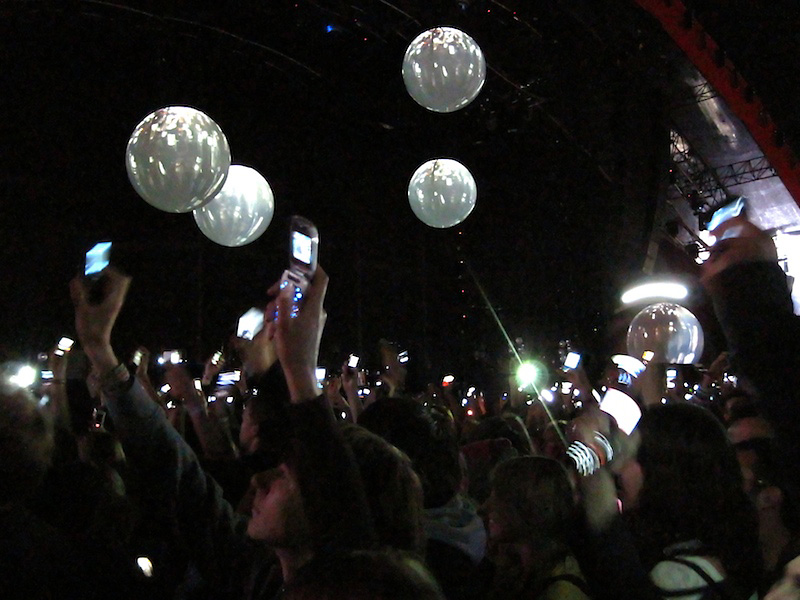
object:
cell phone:
[150, 344, 188, 370]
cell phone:
[162, 348, 183, 367]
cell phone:
[562, 380, 646, 479]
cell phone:
[342, 353, 357, 370]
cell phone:
[613, 366, 638, 390]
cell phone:
[462, 384, 478, 408]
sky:
[2, 9, 797, 362]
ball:
[119, 108, 233, 215]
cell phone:
[278, 214, 321, 324]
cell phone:
[74, 239, 120, 305]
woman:
[615, 398, 765, 595]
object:
[639, 128, 734, 204]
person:
[359, 397, 464, 506]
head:
[241, 423, 427, 555]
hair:
[336, 425, 430, 550]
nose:
[245, 466, 275, 499]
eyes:
[263, 462, 290, 487]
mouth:
[246, 497, 267, 525]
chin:
[246, 518, 269, 540]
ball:
[402, 157, 478, 227]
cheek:
[266, 484, 288, 525]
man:
[81, 262, 422, 599]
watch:
[84, 348, 136, 392]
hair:
[644, 400, 756, 593]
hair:
[366, 405, 460, 492]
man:
[238, 417, 432, 556]